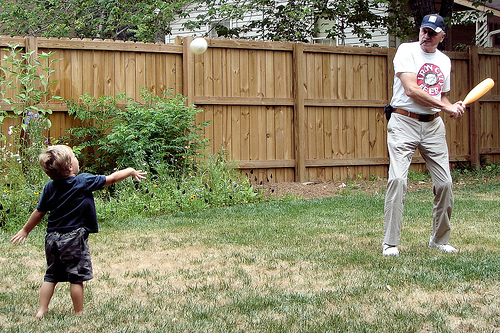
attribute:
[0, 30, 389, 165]
fence — wooden, tall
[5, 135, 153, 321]
child — blonde, young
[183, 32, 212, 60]
ball — white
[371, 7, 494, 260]
man — old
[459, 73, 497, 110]
bat — baseball, yellow, plastic, brown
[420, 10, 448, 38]
hat — black, white, blue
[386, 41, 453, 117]
white shirt — red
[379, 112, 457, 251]
pants — khaki, tans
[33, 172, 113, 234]
shirt — blue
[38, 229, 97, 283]
shorts — gray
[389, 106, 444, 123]
belt — brown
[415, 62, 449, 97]
logo — red